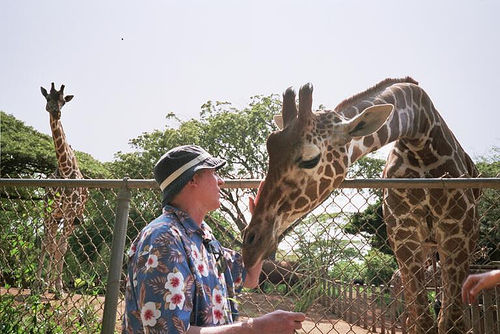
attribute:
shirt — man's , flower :
[130, 204, 241, 332]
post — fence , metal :
[77, 169, 147, 329]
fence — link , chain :
[5, 173, 499, 328]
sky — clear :
[2, 0, 498, 169]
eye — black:
[292, 142, 329, 169]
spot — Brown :
[428, 118, 463, 163]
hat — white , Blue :
[151, 139, 233, 200]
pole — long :
[103, 166, 141, 294]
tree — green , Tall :
[103, 86, 379, 284]